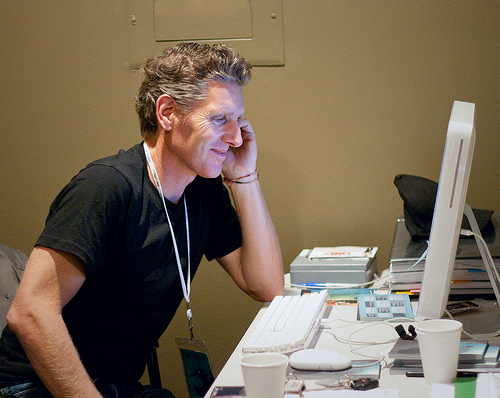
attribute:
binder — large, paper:
[386, 212, 498, 301]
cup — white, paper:
[234, 347, 290, 397]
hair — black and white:
[135, 40, 254, 131]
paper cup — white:
[415, 316, 463, 383]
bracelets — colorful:
[221, 169, 270, 185]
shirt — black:
[41, 147, 255, 364]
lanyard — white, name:
[145, 132, 200, 334]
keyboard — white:
[238, 284, 332, 372]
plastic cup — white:
[414, 315, 465, 384]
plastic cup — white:
[238, 352, 290, 396]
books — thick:
[289, 246, 369, 290]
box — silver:
[287, 241, 380, 286]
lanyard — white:
[140, 138, 205, 330]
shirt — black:
[0, 135, 241, 380]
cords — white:
[313, 305, 484, 368]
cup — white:
[415, 317, 463, 381]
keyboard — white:
[242, 287, 328, 353]